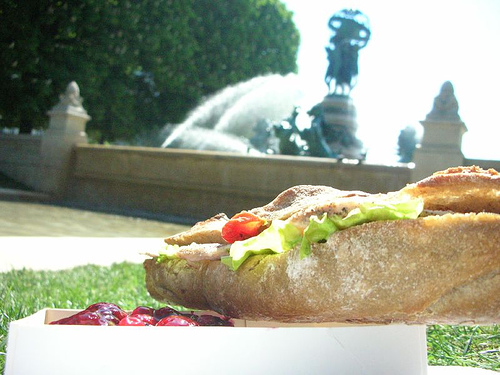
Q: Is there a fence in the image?
A: No, there are no fences.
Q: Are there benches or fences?
A: No, there are no fences or benches.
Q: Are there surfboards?
A: No, there are no surfboards.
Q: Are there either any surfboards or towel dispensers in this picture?
A: No, there are no surfboards or towel dispensers.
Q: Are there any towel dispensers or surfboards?
A: No, there are no surfboards or towel dispensers.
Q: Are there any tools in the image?
A: No, there are no tools.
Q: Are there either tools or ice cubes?
A: No, there are no tools or ice cubes.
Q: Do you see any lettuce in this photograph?
A: Yes, there is lettuce.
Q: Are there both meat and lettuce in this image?
A: Yes, there are both lettuce and meat.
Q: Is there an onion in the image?
A: No, there are no onions.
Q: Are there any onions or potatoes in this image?
A: No, there are no onions or potatoes.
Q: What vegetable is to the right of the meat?
A: The vegetable is lettuce.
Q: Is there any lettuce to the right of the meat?
A: Yes, there is lettuce to the right of the meat.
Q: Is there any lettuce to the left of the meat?
A: No, the lettuce is to the right of the meat.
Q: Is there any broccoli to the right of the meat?
A: No, there is lettuce to the right of the meat.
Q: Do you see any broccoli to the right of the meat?
A: No, there is lettuce to the right of the meat.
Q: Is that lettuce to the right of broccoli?
A: No, the lettuce is to the right of the meat.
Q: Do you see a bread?
A: Yes, there is a bread.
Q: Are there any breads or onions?
A: Yes, there is a bread.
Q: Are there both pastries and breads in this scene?
A: No, there is a bread but no pastries.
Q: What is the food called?
A: The food is a bread.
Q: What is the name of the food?
A: The food is a bread.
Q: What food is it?
A: The food is a bread.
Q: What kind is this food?
A: This is a bread.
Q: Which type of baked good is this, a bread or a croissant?
A: This is a bread.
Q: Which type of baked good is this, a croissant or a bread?
A: This is a bread.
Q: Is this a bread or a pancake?
A: This is a bread.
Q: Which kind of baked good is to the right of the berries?
A: The food is a bread.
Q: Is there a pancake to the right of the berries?
A: No, there is a bread to the right of the berries.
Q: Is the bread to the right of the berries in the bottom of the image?
A: Yes, the bread is to the right of the berries.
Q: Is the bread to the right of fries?
A: No, the bread is to the right of the berries.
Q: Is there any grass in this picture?
A: Yes, there is grass.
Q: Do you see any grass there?
A: Yes, there is grass.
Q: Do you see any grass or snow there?
A: Yes, there is grass.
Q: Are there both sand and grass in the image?
A: No, there is grass but no sand.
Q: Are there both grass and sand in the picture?
A: No, there is grass but no sand.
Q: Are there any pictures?
A: No, there are no pictures.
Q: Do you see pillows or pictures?
A: No, there are no pictures or pillows.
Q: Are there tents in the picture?
A: No, there are no tents.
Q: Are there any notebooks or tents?
A: No, there are no tents or notebooks.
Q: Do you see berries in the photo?
A: Yes, there are berries.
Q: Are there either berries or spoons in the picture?
A: Yes, there are berries.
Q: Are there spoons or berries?
A: Yes, there are berries.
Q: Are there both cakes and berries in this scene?
A: No, there are berries but no cakes.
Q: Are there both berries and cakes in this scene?
A: No, there are berries but no cakes.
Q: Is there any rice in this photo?
A: No, there is no rice.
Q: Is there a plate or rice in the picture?
A: No, there are no rice or plates.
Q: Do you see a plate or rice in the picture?
A: No, there are no rice or plates.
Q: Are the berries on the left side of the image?
A: Yes, the berries are on the left of the image.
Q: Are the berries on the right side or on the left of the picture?
A: The berries are on the left of the image.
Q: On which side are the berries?
A: The berries are on the left of the image.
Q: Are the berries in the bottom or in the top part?
A: The berries are in the bottom of the image.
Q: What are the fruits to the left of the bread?
A: The fruits are berries.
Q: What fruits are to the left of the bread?
A: The fruits are berries.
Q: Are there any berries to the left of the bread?
A: Yes, there are berries to the left of the bread.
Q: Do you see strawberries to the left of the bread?
A: No, there are berries to the left of the bread.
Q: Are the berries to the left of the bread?
A: Yes, the berries are to the left of the bread.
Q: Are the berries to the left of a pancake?
A: No, the berries are to the left of the bread.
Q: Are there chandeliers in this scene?
A: No, there are no chandeliers.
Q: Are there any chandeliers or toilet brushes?
A: No, there are no chandeliers or toilet brushes.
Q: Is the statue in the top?
A: Yes, the statue is in the top of the image.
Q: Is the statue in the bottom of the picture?
A: No, the statue is in the top of the image.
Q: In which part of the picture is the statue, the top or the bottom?
A: The statue is in the top of the image.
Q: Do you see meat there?
A: Yes, there is meat.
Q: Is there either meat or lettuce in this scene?
A: Yes, there is meat.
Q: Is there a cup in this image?
A: No, there are no cups.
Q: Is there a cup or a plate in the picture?
A: No, there are no cups or plates.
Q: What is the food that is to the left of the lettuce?
A: The food is meat.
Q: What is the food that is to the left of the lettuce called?
A: The food is meat.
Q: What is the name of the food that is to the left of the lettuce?
A: The food is meat.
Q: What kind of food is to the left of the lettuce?
A: The food is meat.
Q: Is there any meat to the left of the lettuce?
A: Yes, there is meat to the left of the lettuce.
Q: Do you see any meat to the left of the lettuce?
A: Yes, there is meat to the left of the lettuce.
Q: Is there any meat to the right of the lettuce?
A: No, the meat is to the left of the lettuce.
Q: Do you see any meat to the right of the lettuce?
A: No, the meat is to the left of the lettuce.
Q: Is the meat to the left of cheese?
A: No, the meat is to the left of the lettuce.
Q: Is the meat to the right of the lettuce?
A: No, the meat is to the left of the lettuce.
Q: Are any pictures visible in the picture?
A: No, there are no pictures.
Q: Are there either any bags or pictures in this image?
A: No, there are no pictures or bags.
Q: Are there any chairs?
A: No, there are no chairs.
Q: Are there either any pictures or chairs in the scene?
A: No, there are no chairs or pictures.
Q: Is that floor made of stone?
A: Yes, the floor is made of stone.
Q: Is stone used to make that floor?
A: Yes, the floor is made of stone.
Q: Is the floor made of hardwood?
A: No, the floor is made of stone.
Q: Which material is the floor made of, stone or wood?
A: The floor is made of stone.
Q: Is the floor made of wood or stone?
A: The floor is made of stone.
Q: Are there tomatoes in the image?
A: Yes, there is a tomato.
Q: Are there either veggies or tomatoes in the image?
A: Yes, there is a tomato.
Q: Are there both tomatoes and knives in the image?
A: No, there is a tomato but no knives.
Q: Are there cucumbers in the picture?
A: No, there are no cucumbers.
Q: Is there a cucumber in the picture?
A: No, there are no cucumbers.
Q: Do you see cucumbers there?
A: No, there are no cucumbers.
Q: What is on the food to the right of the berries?
A: The tomato is on the bread.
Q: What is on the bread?
A: The tomato is on the bread.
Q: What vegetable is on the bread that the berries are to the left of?
A: The vegetable is a tomato.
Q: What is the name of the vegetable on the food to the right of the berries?
A: The vegetable is a tomato.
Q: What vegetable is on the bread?
A: The vegetable is a tomato.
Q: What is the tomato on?
A: The tomato is on the bread.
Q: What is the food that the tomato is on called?
A: The food is a bread.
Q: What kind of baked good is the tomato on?
A: The tomato is on the bread.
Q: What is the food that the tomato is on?
A: The food is a bread.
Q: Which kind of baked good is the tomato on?
A: The tomato is on the bread.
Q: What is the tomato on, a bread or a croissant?
A: The tomato is on a bread.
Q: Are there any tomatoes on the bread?
A: Yes, there is a tomato on the bread.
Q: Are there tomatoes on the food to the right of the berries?
A: Yes, there is a tomato on the bread.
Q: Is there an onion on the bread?
A: No, there is a tomato on the bread.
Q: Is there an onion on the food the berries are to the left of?
A: No, there is a tomato on the bread.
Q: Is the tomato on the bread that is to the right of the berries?
A: Yes, the tomato is on the bread.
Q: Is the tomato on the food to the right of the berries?
A: Yes, the tomato is on the bread.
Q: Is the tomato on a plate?
A: No, the tomato is on the bread.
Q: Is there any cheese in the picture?
A: No, there is no cheese.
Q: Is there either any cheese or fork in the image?
A: No, there are no cheese or forks.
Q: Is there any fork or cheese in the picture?
A: No, there are no cheese or forks.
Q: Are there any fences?
A: No, there are no fences.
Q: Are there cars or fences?
A: No, there are no fences or cars.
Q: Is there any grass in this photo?
A: Yes, there is grass.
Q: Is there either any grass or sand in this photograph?
A: Yes, there is grass.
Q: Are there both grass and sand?
A: No, there is grass but no sand.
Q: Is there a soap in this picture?
A: No, there are no soaps.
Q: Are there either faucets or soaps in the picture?
A: No, there are no soaps or faucets.